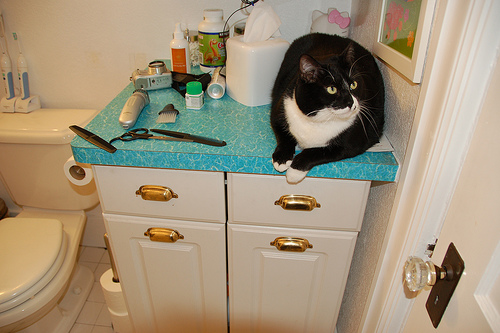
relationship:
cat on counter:
[269, 27, 379, 182] [80, 57, 365, 187]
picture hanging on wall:
[373, 1, 436, 86] [332, 4, 443, 331]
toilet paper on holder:
[56, 140, 98, 186] [92, 222, 123, 278]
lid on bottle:
[180, 76, 211, 97] [179, 75, 206, 112]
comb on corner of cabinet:
[64, 123, 119, 154] [56, 65, 408, 330]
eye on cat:
[325, 85, 336, 94] [269, 27, 379, 182]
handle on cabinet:
[134, 181, 181, 208] [96, 167, 361, 324]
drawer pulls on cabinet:
[273, 195, 320, 212] [83, 160, 372, 332]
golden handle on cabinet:
[141, 224, 190, 249] [64, 44, 404, 329]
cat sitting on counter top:
[269, 27, 379, 182] [172, 100, 269, 160]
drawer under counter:
[109, 178, 250, 250] [112, 109, 402, 189]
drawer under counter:
[224, 170, 370, 235] [65, 52, 400, 183]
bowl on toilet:
[1, 221, 66, 321] [1, 94, 121, 325]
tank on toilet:
[0, 113, 96, 211] [1, 94, 121, 325]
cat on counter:
[270, 32, 385, 184] [65, 52, 400, 183]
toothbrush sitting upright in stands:
[0, 14, 15, 100] [2, 90, 41, 118]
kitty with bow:
[298, 8, 354, 37] [323, 6, 356, 31]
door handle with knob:
[389, 242, 478, 323] [393, 250, 434, 306]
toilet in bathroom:
[1, 104, 112, 328] [4, 5, 494, 332]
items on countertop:
[61, 25, 233, 155] [64, 54, 396, 184]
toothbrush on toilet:
[0, 14, 15, 100] [1, 104, 112, 328]